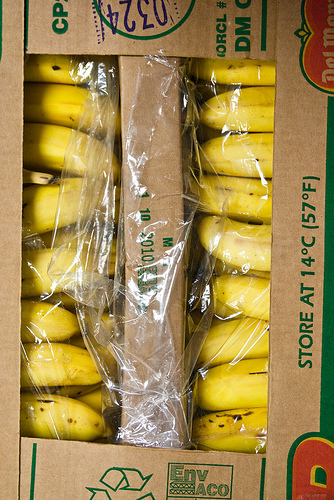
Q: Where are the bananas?
A: In the box.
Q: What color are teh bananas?
A: Yellow.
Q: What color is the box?
A: Brown.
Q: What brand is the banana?
A: Del monte.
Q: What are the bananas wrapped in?
A: Plastic.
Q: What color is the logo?
A: Red.